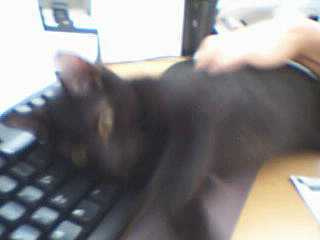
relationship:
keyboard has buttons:
[0, 72, 163, 237] [24, 203, 78, 235]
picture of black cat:
[0, 0, 315, 239] [2, 46, 318, 237]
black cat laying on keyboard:
[2, 46, 318, 237] [0, 103, 135, 239]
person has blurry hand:
[215, 1, 263, 20] [193, 12, 314, 76]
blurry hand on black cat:
[193, 12, 314, 76] [2, 46, 318, 237]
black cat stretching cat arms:
[2, 46, 318, 237] [110, 142, 241, 238]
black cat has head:
[2, 46, 318, 237] [47, 67, 144, 164]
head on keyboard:
[47, 67, 144, 164] [11, 64, 169, 225]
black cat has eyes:
[2, 46, 318, 237] [51, 87, 125, 178]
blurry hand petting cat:
[193, 12, 314, 76] [28, 49, 319, 236]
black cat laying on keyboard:
[2, 46, 318, 237] [1, 75, 142, 238]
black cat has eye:
[2, 46, 318, 237] [97, 104, 115, 136]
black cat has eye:
[2, 46, 318, 237] [70, 143, 87, 172]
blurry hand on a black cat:
[193, 12, 314, 76] [2, 46, 318, 237]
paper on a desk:
[284, 167, 319, 219] [97, 52, 318, 235]